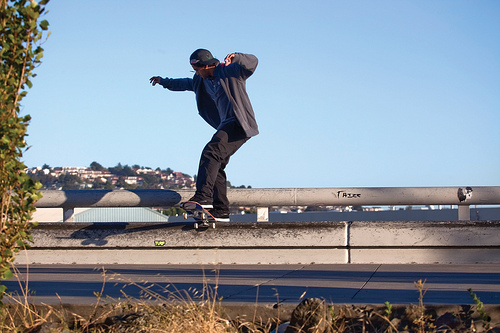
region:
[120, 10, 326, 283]
he is grinding on his skateboard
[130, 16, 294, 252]
he is skate boarding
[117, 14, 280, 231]
he is doing a trick on the railing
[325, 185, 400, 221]
graffiti on the railing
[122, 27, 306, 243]
he is wearing a black baseball cap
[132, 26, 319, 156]
he is wearing a black jacket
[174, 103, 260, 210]
his pants are black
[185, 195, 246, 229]
the soles of his shoe are white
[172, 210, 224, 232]
the wheels of his skateboard are white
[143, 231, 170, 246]
a green sticker on the small wall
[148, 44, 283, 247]
man doing tricks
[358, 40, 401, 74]
white clouds in blue sky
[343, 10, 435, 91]
white clouds in blue sky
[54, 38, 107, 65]
white clouds in blue sky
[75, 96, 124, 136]
white clouds in blue sky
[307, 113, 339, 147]
white clouds in blue sky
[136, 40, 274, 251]
a person skateboarding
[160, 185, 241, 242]
skateboard on concrete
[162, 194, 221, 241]
the bottom of a skateboard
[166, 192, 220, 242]
small tires at the bottom of a skateboard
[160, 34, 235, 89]
a person wearing a cap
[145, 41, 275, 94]
a person with hands up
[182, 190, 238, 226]
Shoes with white soles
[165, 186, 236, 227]
Shoes with white soles on a skateboard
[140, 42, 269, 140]
A man wearing a sweatshirt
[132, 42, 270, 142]
A man wearing a sweatshirt and gray cap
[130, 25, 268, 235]
A young man skateboarding.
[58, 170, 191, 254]
Shadow of a young man skateboarding.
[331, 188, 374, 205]
Graffiti on side of rail.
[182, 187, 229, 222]
Pair of black and white tennis shoes.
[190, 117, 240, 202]
Pair of black pants.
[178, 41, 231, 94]
Young man wearing a black hat.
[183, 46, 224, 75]
A black hat turned backwards.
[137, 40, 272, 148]
Man's arms held out for balance.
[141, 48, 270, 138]
A long sleeve dark shirt.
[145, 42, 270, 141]
Tee shirt underneath long sleeve shirt.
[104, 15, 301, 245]
the man is skateboarding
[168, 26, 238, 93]
the man is wearing a hat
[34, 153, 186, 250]
shadow of the man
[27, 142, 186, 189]
houses in the background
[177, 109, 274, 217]
the pants are black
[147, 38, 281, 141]
the jacket is grey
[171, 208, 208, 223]
the wheels are white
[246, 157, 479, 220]
the rail is grey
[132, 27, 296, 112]
the man is holding his arms out